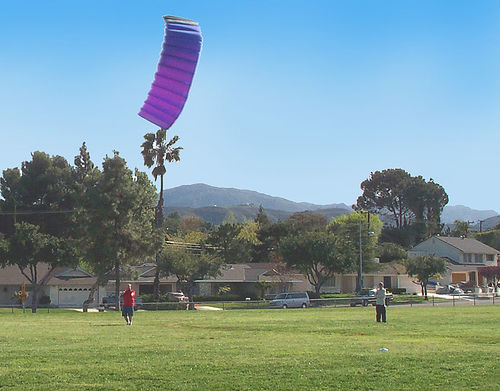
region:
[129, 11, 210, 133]
a purple kite in the sky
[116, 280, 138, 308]
a red tee shirt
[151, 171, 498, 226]
a mountain in the distance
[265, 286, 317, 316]
a gray van on the street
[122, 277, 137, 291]
the head of a man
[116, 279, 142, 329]
a man on the grass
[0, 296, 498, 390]
a green grassy field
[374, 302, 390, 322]
a pair of black pants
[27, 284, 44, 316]
the brown trunk of a tree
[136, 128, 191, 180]
a green palm tree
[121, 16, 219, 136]
A PURPLE KITE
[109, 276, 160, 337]
A MAN IN A RED SHIRT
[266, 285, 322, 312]
A GRAY SUV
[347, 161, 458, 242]
A TREE IN THE DISTANCE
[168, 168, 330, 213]
MOUNTAINS IN THE DISTANCE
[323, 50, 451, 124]
A CLEAR BLUE SKY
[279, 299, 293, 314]
A FRONT CAR TIRE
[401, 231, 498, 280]
A WHITE HOUSE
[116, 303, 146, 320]
A PAIR OF BLUE SHORTS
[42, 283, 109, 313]
A WHITE GARAGE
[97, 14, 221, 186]
purple kite in sky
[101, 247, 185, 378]
man in red shirt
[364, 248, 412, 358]
person in white shirt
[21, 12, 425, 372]
two people in field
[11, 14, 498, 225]
no clouds in sky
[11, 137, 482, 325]
mountain in distance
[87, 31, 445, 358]
one man walking one man flying kite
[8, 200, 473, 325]
houses in photograph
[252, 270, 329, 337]
one vehicle in photograph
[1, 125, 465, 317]
trees in photograph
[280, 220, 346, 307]
A tree in a distance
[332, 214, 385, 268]
A tree in a distance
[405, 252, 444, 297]
A tree in a distance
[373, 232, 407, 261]
A tree in a distance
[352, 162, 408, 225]
A tree in a distance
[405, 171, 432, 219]
A tree in a distance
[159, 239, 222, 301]
A tree in a distance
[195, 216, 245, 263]
A tree in a distance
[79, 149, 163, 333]
A tree in a distance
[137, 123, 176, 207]
A tree in a distance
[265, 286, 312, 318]
A silver van.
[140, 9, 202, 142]
Purple kite in the air.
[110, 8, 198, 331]
Man in red shirt flying a kite.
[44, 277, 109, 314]
Garage attached to home.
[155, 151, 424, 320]
View of mountains from the park.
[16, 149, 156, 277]
Lush trees next to home.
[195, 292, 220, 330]
Driveway into garage.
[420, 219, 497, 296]
Two-story home.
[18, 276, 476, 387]
Green grass in park.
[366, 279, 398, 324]
Man in a grey shirt.